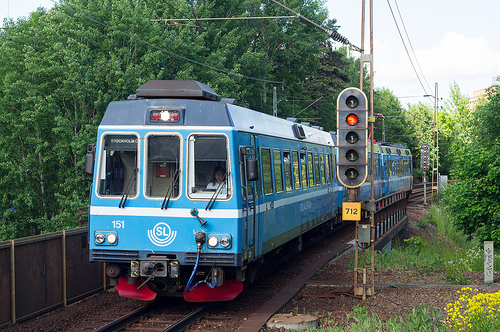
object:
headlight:
[208, 235, 229, 247]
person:
[202, 167, 225, 190]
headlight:
[150, 108, 179, 121]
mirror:
[84, 153, 94, 175]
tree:
[0, 25, 77, 230]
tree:
[447, 77, 500, 240]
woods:
[0, 0, 500, 332]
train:
[82, 80, 413, 303]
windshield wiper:
[205, 171, 229, 211]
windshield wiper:
[161, 169, 180, 210]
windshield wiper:
[118, 166, 136, 209]